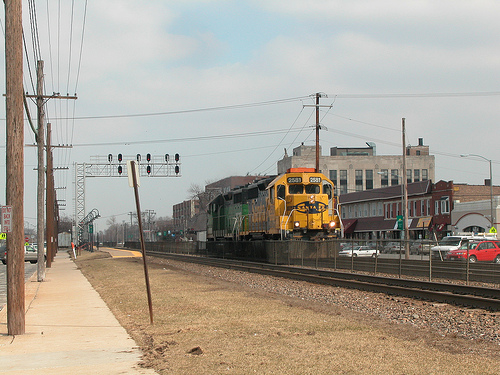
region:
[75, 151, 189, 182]
Traffic signal structure hanging over the tracks.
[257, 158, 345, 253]
Front of the locomotive engine.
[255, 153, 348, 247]
Train car that is painted yellow in front.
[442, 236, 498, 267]
Red car parked in a parking spot.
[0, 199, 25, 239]
Red and white street sign posted.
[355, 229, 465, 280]
Chain link fence separating the tracks.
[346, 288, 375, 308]
Gravel on the ground lining the tracks.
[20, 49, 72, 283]
Row of power lines lining the sidewalk.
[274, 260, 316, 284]
Steel train tracks.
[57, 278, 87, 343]
White cement sidewalk along the street.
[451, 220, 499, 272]
red car parked on the right side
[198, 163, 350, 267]
train on tracks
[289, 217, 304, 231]
front headlight on a train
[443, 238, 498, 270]
red vehicle in a lot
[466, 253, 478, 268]
front wheel on a vehicle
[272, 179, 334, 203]
front windows on a train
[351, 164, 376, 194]
windows on a building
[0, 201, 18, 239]
red and white sign on a post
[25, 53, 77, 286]
utility poles on a sidewalk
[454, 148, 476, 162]
streetlight on a pole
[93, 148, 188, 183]
train signals on a support structure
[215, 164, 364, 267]
the locomotive is yellow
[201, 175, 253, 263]
the cars are black with green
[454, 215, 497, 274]
a small red car is parked by the curb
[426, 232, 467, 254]
a white van is parked next to the red car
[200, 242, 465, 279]
a fence is beside the train track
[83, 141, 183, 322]
this sign appears to be leaning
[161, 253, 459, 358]
it is rock strewn beside the track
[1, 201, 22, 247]
this sign is white with red letters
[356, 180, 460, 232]
this building is made out of brick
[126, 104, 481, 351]
the entire area is pretty dismal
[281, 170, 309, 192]
number 2531 on front of train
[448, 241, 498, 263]
small red car on right of picture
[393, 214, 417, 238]
green sign on pole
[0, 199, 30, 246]
white sign with red letters on pole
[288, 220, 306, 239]
left headlight on train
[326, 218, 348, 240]
right headlight on train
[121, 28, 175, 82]
white clouds in sky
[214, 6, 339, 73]
blue patch of sky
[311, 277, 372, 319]
small rocks along side of train tracks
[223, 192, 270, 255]
green train car